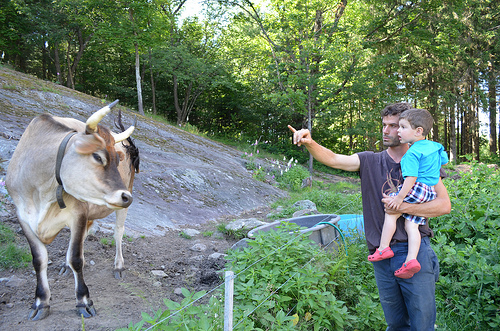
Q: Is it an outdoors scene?
A: Yes, it is outdoors.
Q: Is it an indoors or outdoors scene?
A: It is outdoors.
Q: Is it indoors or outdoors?
A: It is outdoors.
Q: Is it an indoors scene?
A: No, it is outdoors.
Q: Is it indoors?
A: No, it is outdoors.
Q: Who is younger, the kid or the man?
A: The kid is younger than the man.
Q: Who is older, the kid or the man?
A: The man is older than the kid.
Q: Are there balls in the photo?
A: No, there are no balls.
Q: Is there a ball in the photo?
A: No, there are no balls.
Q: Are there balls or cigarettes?
A: No, there are no balls or cigarettes.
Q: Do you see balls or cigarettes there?
A: No, there are no balls or cigarettes.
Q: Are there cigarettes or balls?
A: No, there are no balls or cigarettes.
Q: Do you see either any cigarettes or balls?
A: No, there are no balls or cigarettes.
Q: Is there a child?
A: Yes, there is a child.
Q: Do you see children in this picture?
A: Yes, there is a child.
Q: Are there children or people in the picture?
A: Yes, there is a child.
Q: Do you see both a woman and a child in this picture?
A: No, there is a child but no women.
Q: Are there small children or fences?
A: Yes, there is a small child.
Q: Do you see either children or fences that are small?
A: Yes, the child is small.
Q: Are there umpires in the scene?
A: No, there are no umpires.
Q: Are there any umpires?
A: No, there are no umpires.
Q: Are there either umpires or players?
A: No, there are no umpires or players.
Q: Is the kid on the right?
A: Yes, the kid is on the right of the image.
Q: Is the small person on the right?
A: Yes, the kid is on the right of the image.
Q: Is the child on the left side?
A: No, the child is on the right of the image.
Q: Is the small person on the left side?
A: No, the child is on the right of the image.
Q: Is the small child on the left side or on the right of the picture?
A: The child is on the right of the image.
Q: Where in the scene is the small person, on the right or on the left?
A: The child is on the right of the image.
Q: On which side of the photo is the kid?
A: The kid is on the right of the image.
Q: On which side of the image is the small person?
A: The kid is on the right of the image.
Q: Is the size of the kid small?
A: Yes, the kid is small.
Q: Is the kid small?
A: Yes, the kid is small.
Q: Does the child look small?
A: Yes, the child is small.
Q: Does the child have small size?
A: Yes, the child is small.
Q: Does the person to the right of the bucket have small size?
A: Yes, the child is small.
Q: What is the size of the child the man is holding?
A: The child is small.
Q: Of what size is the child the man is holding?
A: The child is small.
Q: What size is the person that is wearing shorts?
A: The child is small.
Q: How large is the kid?
A: The kid is small.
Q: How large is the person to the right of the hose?
A: The kid is small.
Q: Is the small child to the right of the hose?
A: Yes, the child is to the right of the hose.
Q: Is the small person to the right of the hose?
A: Yes, the child is to the right of the hose.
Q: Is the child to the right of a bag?
A: No, the child is to the right of the hose.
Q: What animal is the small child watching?
A: The kid is watching the cow.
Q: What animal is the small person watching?
A: The kid is watching the cow.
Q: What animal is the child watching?
A: The kid is watching the cow.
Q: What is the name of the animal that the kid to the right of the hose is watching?
A: The animal is a cow.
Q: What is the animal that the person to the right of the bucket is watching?
A: The animal is a cow.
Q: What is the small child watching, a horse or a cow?
A: The child is watching a cow.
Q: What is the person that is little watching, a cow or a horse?
A: The child is watching a cow.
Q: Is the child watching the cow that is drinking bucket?
A: Yes, the child is watching the cow.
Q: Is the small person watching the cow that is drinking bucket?
A: Yes, the child is watching the cow.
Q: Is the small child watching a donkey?
A: No, the child is watching the cow.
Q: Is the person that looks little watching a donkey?
A: No, the child is watching the cow.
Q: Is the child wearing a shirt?
A: Yes, the child is wearing a shirt.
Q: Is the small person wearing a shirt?
A: Yes, the child is wearing a shirt.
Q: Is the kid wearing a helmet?
A: No, the kid is wearing a shirt.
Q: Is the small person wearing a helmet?
A: No, the kid is wearing a shirt.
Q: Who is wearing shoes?
A: The child is wearing shoes.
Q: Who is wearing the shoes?
A: The child is wearing shoes.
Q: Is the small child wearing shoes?
A: Yes, the child is wearing shoes.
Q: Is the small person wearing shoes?
A: Yes, the child is wearing shoes.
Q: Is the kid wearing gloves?
A: No, the kid is wearing shoes.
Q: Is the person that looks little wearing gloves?
A: No, the kid is wearing shoes.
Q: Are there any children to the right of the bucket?
A: Yes, there is a child to the right of the bucket.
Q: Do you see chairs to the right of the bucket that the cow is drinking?
A: No, there is a child to the right of the bucket.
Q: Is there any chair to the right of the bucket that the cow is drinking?
A: No, there is a child to the right of the bucket.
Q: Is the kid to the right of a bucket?
A: Yes, the kid is to the right of a bucket.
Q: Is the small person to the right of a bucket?
A: Yes, the kid is to the right of a bucket.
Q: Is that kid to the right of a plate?
A: No, the kid is to the right of a bucket.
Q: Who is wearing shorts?
A: The child is wearing shorts.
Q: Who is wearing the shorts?
A: The child is wearing shorts.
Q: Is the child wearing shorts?
A: Yes, the child is wearing shorts.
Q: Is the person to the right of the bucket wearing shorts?
A: Yes, the child is wearing shorts.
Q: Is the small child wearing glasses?
A: No, the child is wearing shorts.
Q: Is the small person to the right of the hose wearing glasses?
A: No, the child is wearing shorts.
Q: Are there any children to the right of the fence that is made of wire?
A: Yes, there is a child to the right of the fence.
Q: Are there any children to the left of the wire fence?
A: No, the child is to the right of the fence.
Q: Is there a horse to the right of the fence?
A: No, there is a child to the right of the fence.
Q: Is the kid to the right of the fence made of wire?
A: Yes, the kid is to the right of the fence.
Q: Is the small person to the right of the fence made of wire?
A: Yes, the kid is to the right of the fence.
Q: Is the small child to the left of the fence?
A: No, the child is to the right of the fence.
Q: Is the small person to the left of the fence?
A: No, the child is to the right of the fence.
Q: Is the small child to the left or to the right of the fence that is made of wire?
A: The child is to the right of the fence.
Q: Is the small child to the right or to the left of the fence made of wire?
A: The child is to the right of the fence.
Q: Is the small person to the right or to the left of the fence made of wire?
A: The child is to the right of the fence.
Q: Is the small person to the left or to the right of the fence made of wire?
A: The child is to the right of the fence.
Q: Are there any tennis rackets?
A: No, there are no tennis rackets.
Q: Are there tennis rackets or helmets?
A: No, there are no tennis rackets or helmets.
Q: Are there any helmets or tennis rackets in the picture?
A: No, there are no tennis rackets or helmets.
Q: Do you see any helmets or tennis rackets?
A: No, there are no tennis rackets or helmets.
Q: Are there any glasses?
A: No, there are no glasses.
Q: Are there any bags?
A: No, there are no bags.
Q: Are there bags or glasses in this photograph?
A: No, there are no bags or glasses.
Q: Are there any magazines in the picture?
A: No, there are no magazines.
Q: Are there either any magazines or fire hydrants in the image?
A: No, there are no magazines or fire hydrants.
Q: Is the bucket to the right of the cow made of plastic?
A: Yes, the bucket is made of plastic.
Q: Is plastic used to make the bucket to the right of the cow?
A: Yes, the bucket is made of plastic.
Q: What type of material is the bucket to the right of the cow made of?
A: The bucket is made of plastic.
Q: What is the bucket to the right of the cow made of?
A: The bucket is made of plastic.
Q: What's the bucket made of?
A: The bucket is made of plastic.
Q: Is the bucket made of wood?
A: No, the bucket is made of plastic.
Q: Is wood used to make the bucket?
A: No, the bucket is made of plastic.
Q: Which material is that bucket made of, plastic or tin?
A: The bucket is made of plastic.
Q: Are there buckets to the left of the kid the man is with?
A: Yes, there is a bucket to the left of the kid.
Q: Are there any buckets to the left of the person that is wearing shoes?
A: Yes, there is a bucket to the left of the kid.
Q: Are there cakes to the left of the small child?
A: No, there is a bucket to the left of the child.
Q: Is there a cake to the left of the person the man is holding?
A: No, there is a bucket to the left of the child.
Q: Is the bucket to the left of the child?
A: Yes, the bucket is to the left of the child.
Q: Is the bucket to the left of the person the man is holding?
A: Yes, the bucket is to the left of the child.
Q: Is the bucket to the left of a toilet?
A: No, the bucket is to the left of the child.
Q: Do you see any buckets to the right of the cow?
A: Yes, there is a bucket to the right of the cow.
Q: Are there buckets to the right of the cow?
A: Yes, there is a bucket to the right of the cow.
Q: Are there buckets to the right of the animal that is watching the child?
A: Yes, there is a bucket to the right of the cow.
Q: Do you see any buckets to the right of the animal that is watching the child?
A: Yes, there is a bucket to the right of the cow.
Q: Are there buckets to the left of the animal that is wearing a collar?
A: No, the bucket is to the right of the cow.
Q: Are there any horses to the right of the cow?
A: No, there is a bucket to the right of the cow.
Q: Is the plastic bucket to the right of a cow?
A: Yes, the bucket is to the right of a cow.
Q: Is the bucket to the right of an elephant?
A: No, the bucket is to the right of a cow.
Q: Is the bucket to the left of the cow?
A: No, the bucket is to the right of the cow.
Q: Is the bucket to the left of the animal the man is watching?
A: No, the bucket is to the right of the cow.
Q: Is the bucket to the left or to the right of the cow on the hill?
A: The bucket is to the right of the cow.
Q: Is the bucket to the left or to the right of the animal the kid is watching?
A: The bucket is to the right of the cow.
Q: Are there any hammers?
A: No, there are no hammers.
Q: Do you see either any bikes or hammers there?
A: No, there are no hammers or bikes.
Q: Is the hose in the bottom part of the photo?
A: Yes, the hose is in the bottom of the image.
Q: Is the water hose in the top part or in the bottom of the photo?
A: The water hose is in the bottom of the image.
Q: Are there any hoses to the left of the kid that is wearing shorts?
A: Yes, there is a hose to the left of the child.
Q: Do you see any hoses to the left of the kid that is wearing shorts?
A: Yes, there is a hose to the left of the child.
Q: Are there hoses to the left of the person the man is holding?
A: Yes, there is a hose to the left of the child.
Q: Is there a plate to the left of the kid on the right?
A: No, there is a hose to the left of the kid.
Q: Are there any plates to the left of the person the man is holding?
A: No, there is a hose to the left of the kid.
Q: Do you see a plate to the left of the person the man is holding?
A: No, there is a hose to the left of the kid.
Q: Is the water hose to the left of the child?
A: Yes, the water hose is to the left of the child.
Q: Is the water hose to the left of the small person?
A: Yes, the water hose is to the left of the child.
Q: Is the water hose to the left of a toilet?
A: No, the water hose is to the left of the child.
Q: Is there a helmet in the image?
A: No, there are no helmets.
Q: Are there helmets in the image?
A: No, there are no helmets.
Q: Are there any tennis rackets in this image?
A: No, there are no tennis rackets.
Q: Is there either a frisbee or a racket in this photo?
A: No, there are no rackets or frisbees.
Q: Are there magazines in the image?
A: No, there are no magazines.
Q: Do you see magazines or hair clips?
A: No, there are no magazines or hair clips.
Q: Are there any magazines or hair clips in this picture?
A: No, there are no magazines or hair clips.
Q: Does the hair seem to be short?
A: Yes, the hair is short.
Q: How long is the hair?
A: The hair is short.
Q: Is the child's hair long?
A: No, the hair is short.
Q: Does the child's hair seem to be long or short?
A: The hair is short.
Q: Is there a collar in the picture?
A: Yes, there is a collar.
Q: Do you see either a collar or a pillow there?
A: Yes, there is a collar.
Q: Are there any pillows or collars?
A: Yes, there is a collar.